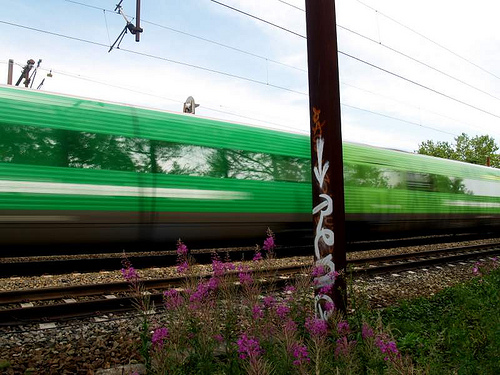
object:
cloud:
[0, 0, 499, 154]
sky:
[0, 0, 499, 169]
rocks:
[37, 300, 43, 304]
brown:
[0, 296, 14, 301]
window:
[153, 139, 225, 178]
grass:
[122, 267, 499, 374]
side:
[0, 84, 499, 225]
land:
[0, 233, 499, 374]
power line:
[0, 20, 459, 137]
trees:
[414, 132, 499, 169]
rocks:
[374, 276, 382, 280]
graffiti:
[310, 136, 329, 189]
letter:
[313, 227, 334, 258]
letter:
[311, 252, 334, 285]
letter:
[314, 294, 334, 321]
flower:
[303, 315, 329, 334]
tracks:
[0, 242, 499, 303]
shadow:
[0, 209, 499, 259]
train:
[0, 84, 499, 256]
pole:
[304, 0, 348, 320]